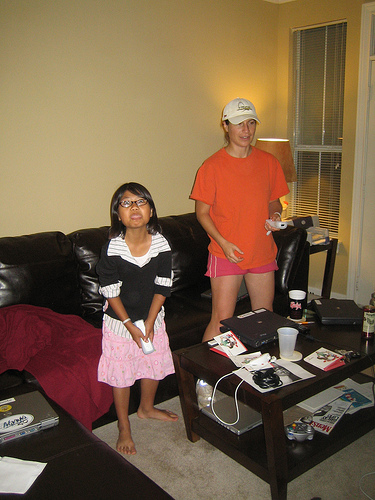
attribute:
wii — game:
[266, 217, 295, 229]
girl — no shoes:
[93, 276, 172, 312]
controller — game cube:
[117, 321, 153, 355]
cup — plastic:
[276, 325, 306, 365]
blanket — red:
[5, 324, 92, 379]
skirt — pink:
[96, 351, 177, 380]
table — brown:
[210, 334, 356, 412]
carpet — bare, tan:
[176, 468, 240, 494]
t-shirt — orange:
[199, 160, 289, 243]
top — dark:
[84, 232, 164, 313]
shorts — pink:
[195, 262, 279, 280]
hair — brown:
[134, 180, 160, 196]